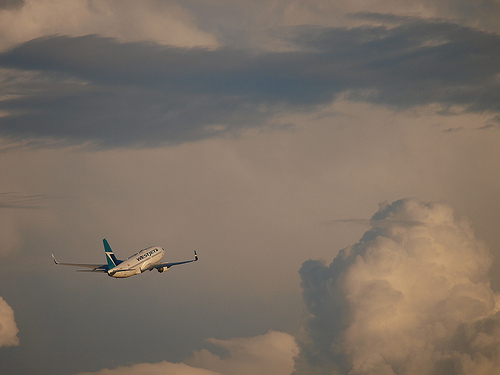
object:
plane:
[49, 236, 200, 280]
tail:
[77, 259, 139, 277]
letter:
[144, 249, 149, 259]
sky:
[155, 100, 280, 157]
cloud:
[298, 196, 497, 374]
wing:
[159, 251, 201, 271]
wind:
[208, 299, 245, 325]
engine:
[158, 263, 170, 274]